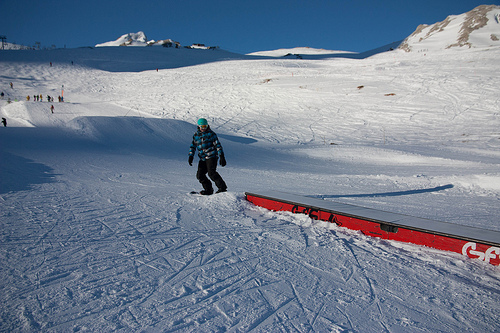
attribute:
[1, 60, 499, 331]
lines — many, tracks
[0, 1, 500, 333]
snow — white, tracked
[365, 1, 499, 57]
mountain — deserted, just empty, largely snow-covered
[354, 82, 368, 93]
spot — brown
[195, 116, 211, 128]
cap — turquoise, blue, green, aqua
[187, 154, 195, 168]
glove — black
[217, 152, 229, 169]
glove — black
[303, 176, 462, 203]
shadow — elongated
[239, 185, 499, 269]
thing — red, barrier, jump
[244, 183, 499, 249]
edge — black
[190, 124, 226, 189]
clothes — for snowboarding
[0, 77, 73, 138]
people — waiting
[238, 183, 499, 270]
barrier — thing, for snowboarding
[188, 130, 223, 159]
coat — winter coat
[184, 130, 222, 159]
jacket — coat, winter jacket, striped, plaid, blue+black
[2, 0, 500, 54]
sky — blue, clear, steel blue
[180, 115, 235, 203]
snowboarder — anticipating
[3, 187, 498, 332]
tracks — straight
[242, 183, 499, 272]
jump — red, large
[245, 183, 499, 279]
ramp — jump, metal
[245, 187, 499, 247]
surface — metal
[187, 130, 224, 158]
plaid — blue based, checked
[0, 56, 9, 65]
ski lift — possible but unseen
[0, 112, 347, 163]
shadow — large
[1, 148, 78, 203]
shadow — variegated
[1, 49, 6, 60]
mountain — unseen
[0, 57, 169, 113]
people — small cos far away